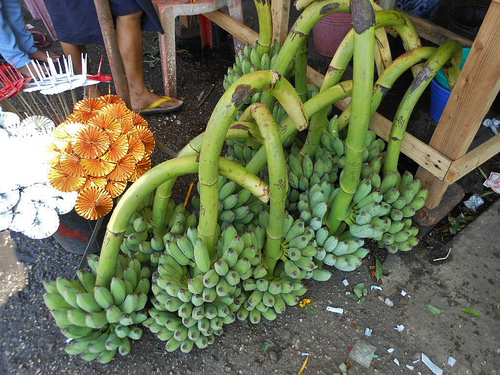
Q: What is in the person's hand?
A: Poles.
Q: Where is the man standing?
A: Beside a plastic chair.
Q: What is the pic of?
A: Bananas.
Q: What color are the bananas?
A: Green.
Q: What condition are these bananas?
A: Unripe.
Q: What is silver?
A: Flowers.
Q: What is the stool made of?
A: Plastic.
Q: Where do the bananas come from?
A: Banana tree.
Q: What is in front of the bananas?
A: Trash.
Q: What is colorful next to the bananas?
A: Flowers.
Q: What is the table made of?
A: Wood.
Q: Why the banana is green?
A: It's not ripe.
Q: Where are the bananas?
A: On the ground.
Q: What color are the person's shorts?
A: Blue.